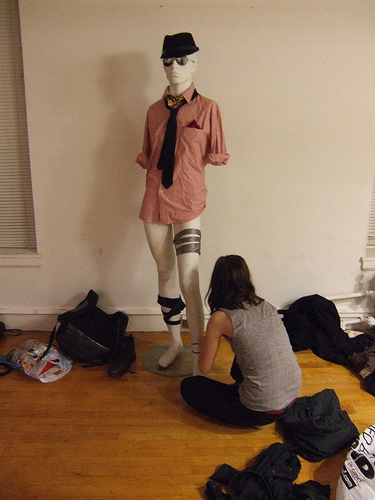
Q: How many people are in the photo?
A: One.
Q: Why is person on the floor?
A: Working.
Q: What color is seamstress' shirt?
A: Grey.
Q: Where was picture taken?
A: In a room.